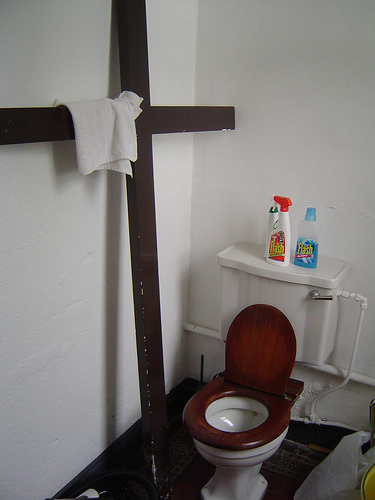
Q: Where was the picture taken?
A: It was taken at the bathroom.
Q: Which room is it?
A: It is a bathroom.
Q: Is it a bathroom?
A: Yes, it is a bathroom.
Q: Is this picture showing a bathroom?
A: Yes, it is showing a bathroom.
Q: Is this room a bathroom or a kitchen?
A: It is a bathroom.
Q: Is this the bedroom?
A: No, it is the bathroom.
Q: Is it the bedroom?
A: No, it is the bathroom.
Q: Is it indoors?
A: Yes, it is indoors.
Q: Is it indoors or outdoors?
A: It is indoors.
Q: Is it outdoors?
A: No, it is indoors.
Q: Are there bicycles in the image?
A: No, there are no bicycles.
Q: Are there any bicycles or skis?
A: No, there are no bicycles or skis.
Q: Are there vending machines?
A: No, there are no vending machines.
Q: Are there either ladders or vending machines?
A: No, there are no vending machines or ladders.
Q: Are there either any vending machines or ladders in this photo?
A: No, there are no vending machines or ladders.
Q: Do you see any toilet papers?
A: No, there are no toilet papers.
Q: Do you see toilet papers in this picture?
A: No, there are no toilet papers.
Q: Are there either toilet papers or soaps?
A: No, there are no toilet papers or soaps.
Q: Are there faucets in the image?
A: No, there are no faucets.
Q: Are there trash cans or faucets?
A: No, there are no faucets or trash cans.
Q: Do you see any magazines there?
A: No, there are no magazines.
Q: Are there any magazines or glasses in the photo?
A: No, there are no magazines or glasses.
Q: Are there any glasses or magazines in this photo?
A: No, there are no magazines or glasses.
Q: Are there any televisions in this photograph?
A: No, there are no televisions.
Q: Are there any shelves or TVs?
A: No, there are no TVs or shelves.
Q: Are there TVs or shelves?
A: No, there are no TVs or shelves.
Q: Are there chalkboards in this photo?
A: No, there are no chalkboards.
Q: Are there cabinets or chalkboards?
A: No, there are no chalkboards or cabinets.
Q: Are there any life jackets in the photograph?
A: No, there are no life jackets.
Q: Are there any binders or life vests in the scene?
A: No, there are no life vests or binders.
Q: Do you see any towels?
A: Yes, there is a towel.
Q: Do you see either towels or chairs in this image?
A: Yes, there is a towel.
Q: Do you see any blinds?
A: No, there are no blinds.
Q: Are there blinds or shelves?
A: No, there are no blinds or shelves.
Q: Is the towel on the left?
A: Yes, the towel is on the left of the image.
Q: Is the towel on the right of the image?
A: No, the towel is on the left of the image.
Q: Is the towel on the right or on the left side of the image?
A: The towel is on the left of the image.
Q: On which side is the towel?
A: The towel is on the left of the image.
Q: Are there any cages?
A: No, there are no cages.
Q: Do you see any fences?
A: No, there are no fences.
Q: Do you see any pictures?
A: No, there are no pictures.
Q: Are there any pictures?
A: No, there are no pictures.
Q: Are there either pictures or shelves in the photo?
A: No, there are no pictures or shelves.